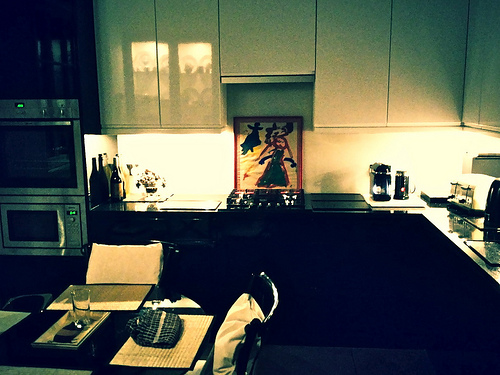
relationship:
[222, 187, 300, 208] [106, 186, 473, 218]
stove on counter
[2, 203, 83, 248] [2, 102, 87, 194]
microwave beneath oven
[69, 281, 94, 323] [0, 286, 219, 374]
cup on dinner table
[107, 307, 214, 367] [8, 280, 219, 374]
tablecloth on dinner table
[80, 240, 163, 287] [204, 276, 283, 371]
cushion on chair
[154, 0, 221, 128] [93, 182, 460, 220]
cabinet above counter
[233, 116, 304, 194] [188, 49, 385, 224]
photo on wall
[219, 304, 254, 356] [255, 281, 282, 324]
pillow in chair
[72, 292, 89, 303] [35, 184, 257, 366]
glass on table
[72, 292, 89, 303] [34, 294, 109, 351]
glass in bowl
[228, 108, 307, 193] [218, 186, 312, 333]
photo over stove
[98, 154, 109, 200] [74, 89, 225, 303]
bottle on counter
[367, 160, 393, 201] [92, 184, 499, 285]
coffe pot on counter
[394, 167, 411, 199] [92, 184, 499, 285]
coffe pot on counter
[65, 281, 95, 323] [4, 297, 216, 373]
glass on table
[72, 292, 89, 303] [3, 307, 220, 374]
glass on table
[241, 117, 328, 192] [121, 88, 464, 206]
art on wall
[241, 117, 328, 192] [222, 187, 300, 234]
art behind stove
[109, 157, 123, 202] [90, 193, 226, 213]
bottle on counter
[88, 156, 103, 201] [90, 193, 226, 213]
bottle on counter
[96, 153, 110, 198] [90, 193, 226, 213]
bottle on counter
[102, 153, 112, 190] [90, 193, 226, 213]
bottle on counter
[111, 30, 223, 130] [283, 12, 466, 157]
reflection on cabinet doors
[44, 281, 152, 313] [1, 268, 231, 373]
placemat on table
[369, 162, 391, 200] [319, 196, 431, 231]
coffe pot on counter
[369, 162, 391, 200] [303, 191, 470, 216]
coffe pot on counter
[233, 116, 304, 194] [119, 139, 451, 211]
photo on wall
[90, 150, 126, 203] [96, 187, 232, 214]
bottles on counter top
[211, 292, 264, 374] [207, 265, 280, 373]
pillow sitting on chair